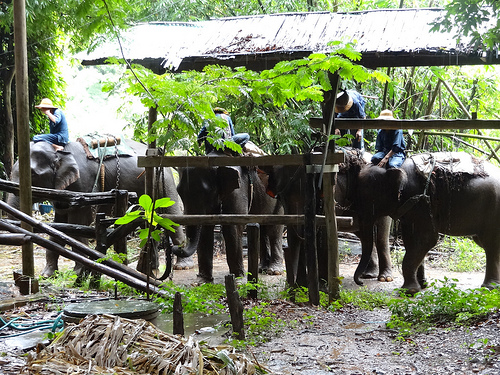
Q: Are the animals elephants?
A: Yes, all the animals are elephants.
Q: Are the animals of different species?
A: No, all the animals are elephants.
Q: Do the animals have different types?
A: No, all the animals are elephants.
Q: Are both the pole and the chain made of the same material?
A: No, the pole is made of wood and the chain is made of metal.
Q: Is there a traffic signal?
A: No, there are no traffic lights.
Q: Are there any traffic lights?
A: No, there are no traffic lights.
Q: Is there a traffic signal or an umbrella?
A: No, there are no traffic lights or umbrellas.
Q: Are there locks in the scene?
A: No, there are no locks.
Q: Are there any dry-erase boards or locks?
A: No, there are no locks or dry-erase boards.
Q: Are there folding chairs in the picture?
A: No, there are no folding chairs.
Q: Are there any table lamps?
A: No, there are no table lamps.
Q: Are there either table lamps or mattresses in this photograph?
A: No, there are no table lamps or mattresses.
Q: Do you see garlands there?
A: No, there are no garlands.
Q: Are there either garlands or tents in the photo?
A: No, there are no garlands or tents.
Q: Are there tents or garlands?
A: No, there are no garlands or tents.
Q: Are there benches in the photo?
A: No, there are no benches.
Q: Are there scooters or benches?
A: No, there are no benches or scooters.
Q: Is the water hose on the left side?
A: Yes, the water hose is on the left of the image.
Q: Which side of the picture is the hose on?
A: The hose is on the left of the image.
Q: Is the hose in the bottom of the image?
A: Yes, the hose is in the bottom of the image.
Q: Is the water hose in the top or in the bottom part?
A: The water hose is in the bottom of the image.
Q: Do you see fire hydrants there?
A: No, there are no fire hydrants.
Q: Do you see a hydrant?
A: No, there are no fire hydrants.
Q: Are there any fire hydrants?
A: No, there are no fire hydrants.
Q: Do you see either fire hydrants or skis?
A: No, there are no fire hydrants or skis.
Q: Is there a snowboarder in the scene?
A: No, there are no snowboarders.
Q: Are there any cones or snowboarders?
A: No, there are no snowboarders or cones.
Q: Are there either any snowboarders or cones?
A: No, there are no snowboarders or cones.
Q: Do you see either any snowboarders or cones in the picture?
A: No, there are no snowboarders or cones.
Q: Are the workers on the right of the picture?
A: Yes, the workers are on the right of the image.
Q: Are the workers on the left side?
A: No, the workers are on the right of the image.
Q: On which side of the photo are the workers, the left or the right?
A: The workers are on the right of the image.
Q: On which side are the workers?
A: The workers are on the right of the image.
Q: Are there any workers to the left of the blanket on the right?
A: Yes, there are workers to the left of the blanket.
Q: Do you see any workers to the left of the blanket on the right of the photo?
A: Yes, there are workers to the left of the blanket.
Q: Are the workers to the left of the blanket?
A: Yes, the workers are to the left of the blanket.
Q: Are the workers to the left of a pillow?
A: No, the workers are to the left of the blanket.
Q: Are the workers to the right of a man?
A: Yes, the workers are to the right of a man.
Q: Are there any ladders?
A: No, there are no ladders.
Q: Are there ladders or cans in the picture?
A: No, there are no ladders or cans.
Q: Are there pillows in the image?
A: No, there are no pillows.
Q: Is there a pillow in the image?
A: No, there are no pillows.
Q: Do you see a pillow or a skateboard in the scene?
A: No, there are no pillows or skateboards.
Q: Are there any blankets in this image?
A: Yes, there is a blanket.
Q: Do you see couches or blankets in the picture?
A: Yes, there is a blanket.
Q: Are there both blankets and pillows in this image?
A: No, there is a blanket but no pillows.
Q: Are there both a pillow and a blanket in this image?
A: No, there is a blanket but no pillows.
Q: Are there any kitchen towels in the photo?
A: No, there are no kitchen towels.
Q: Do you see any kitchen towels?
A: No, there are no kitchen towels.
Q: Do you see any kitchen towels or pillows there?
A: No, there are no kitchen towels or pillows.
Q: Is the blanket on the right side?
A: Yes, the blanket is on the right of the image.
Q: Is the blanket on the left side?
A: No, the blanket is on the right of the image.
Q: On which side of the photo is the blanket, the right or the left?
A: The blanket is on the right of the image.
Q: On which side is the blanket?
A: The blanket is on the right of the image.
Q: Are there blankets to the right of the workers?
A: Yes, there is a blanket to the right of the workers.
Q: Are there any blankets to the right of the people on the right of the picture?
A: Yes, there is a blanket to the right of the workers.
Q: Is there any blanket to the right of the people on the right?
A: Yes, there is a blanket to the right of the workers.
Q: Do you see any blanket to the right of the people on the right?
A: Yes, there is a blanket to the right of the workers.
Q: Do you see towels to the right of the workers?
A: No, there is a blanket to the right of the workers.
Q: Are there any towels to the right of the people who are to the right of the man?
A: No, there is a blanket to the right of the workers.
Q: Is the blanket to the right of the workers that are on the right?
A: Yes, the blanket is to the right of the workers.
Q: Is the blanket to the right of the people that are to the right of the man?
A: Yes, the blanket is to the right of the workers.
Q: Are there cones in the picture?
A: No, there are no cones.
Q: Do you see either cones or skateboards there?
A: No, there are no cones or skateboards.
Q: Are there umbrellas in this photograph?
A: No, there are no umbrellas.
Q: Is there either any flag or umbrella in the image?
A: No, there are no umbrellas or flags.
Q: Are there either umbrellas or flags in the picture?
A: No, there are no umbrellas or flags.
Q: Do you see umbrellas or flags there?
A: No, there are no umbrellas or flags.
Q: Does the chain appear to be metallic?
A: Yes, the chain is metallic.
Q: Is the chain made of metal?
A: Yes, the chain is made of metal.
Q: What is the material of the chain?
A: The chain is made of metal.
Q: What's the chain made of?
A: The chain is made of metal.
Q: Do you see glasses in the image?
A: No, there are no glasses.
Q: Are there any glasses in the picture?
A: No, there are no glasses.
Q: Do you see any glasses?
A: No, there are no glasses.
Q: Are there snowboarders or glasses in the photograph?
A: No, there are no glasses or snowboarders.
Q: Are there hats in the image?
A: Yes, there is a hat.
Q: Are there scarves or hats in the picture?
A: Yes, there is a hat.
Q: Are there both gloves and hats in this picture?
A: No, there is a hat but no gloves.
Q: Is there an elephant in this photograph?
A: Yes, there are elephants.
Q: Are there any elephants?
A: Yes, there are elephants.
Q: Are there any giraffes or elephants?
A: Yes, there are elephants.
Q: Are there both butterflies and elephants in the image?
A: No, there are elephants but no butterflies.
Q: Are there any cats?
A: No, there are no cats.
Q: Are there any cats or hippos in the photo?
A: No, there are no cats or hippos.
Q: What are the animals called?
A: The animals are elephants.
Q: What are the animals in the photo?
A: The animals are elephants.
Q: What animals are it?
A: The animals are elephants.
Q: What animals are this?
A: These are elephants.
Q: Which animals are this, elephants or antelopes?
A: These are elephants.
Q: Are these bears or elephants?
A: These are elephants.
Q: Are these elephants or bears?
A: These are elephants.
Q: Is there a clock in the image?
A: No, there are no clocks.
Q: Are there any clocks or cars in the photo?
A: No, there are no clocks or cars.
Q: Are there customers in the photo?
A: No, there are no customers.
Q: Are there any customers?
A: No, there are no customers.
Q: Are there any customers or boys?
A: No, there are no customers or boys.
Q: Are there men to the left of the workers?
A: Yes, there is a man to the left of the workers.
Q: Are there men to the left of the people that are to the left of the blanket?
A: Yes, there is a man to the left of the workers.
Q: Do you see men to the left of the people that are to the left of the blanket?
A: Yes, there is a man to the left of the workers.